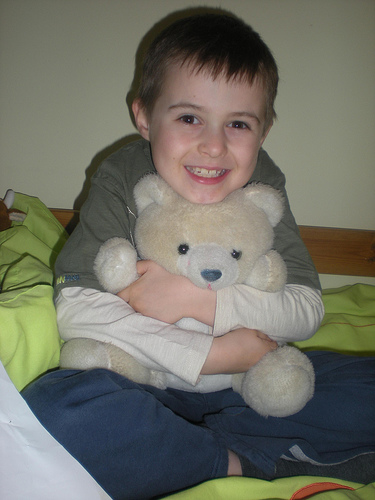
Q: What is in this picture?
A: A boy with his bear.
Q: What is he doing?
A: Hugging the bear.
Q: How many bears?
A: One bear.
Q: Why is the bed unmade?
A: Boy is playing on the bed.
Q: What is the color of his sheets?
A: Green.